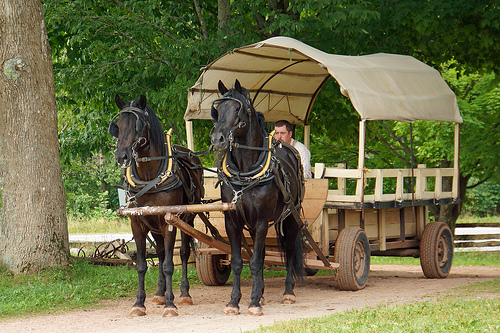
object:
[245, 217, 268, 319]
leg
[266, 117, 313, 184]
man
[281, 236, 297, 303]
leg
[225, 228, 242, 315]
leg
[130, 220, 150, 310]
leg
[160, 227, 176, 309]
leg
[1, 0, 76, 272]
tree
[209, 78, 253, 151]
head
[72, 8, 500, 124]
tree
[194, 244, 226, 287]
wheel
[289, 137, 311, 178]
shirt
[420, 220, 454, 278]
wheel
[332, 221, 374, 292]
wheel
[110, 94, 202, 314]
horse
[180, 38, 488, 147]
shade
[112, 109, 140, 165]
face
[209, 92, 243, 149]
face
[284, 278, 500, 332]
grass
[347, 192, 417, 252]
man horse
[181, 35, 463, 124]
canopy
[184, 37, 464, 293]
carriage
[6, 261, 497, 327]
path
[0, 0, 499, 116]
background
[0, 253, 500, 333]
field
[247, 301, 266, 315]
hooves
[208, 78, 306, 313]
horse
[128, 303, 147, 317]
hooves